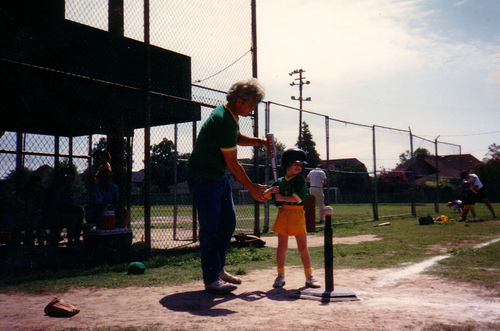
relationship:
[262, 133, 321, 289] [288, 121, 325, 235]
batter standing beside tree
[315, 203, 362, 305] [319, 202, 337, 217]
tee with ball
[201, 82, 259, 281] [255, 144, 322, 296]
man helping batter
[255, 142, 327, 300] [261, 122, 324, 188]
batter wearing helmet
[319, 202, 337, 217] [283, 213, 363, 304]
ball on tee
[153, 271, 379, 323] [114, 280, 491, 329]
shadows on dirt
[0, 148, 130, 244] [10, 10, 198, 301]
players in dugout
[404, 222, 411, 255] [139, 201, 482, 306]
grass on field